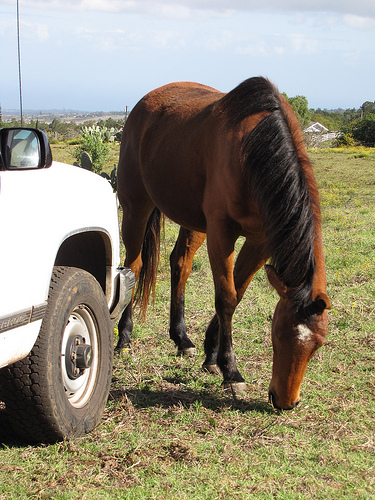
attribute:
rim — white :
[62, 302, 99, 410]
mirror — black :
[2, 125, 52, 168]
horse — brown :
[111, 76, 333, 410]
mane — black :
[243, 102, 319, 314]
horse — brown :
[113, 76, 368, 468]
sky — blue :
[1, 0, 373, 115]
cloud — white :
[22, 4, 257, 33]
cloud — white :
[39, 23, 181, 65]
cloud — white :
[10, 14, 128, 58]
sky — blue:
[82, 7, 313, 82]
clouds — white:
[164, 4, 279, 59]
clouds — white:
[173, 7, 242, 58]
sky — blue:
[70, 8, 318, 70]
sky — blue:
[93, 18, 263, 76]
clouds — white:
[69, 22, 143, 76]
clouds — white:
[39, 21, 128, 68]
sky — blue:
[39, 5, 221, 65]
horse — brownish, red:
[88, 68, 335, 428]